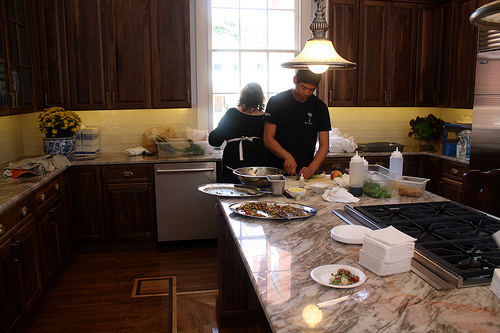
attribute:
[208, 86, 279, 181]
woman — inside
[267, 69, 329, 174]
man — inside, slicing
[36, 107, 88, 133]
flower — yellow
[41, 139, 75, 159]
pot — blue, white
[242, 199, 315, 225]
tray — metal, empty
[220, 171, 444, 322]
counter — island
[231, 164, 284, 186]
basin — metal, large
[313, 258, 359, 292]
plate — white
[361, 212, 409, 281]
napkins — white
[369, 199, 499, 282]
stove — six-burner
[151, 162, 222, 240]
dishwasher — stainless steel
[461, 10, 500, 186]
refrigerator — stainless steel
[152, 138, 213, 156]
containers — plastic